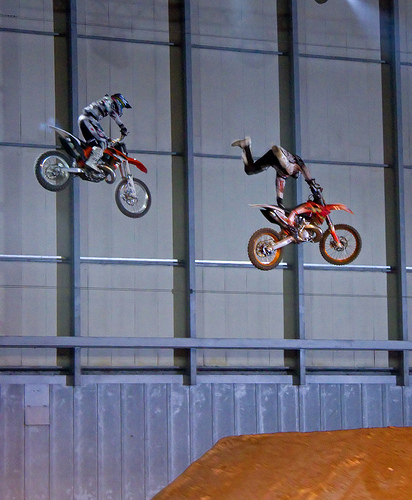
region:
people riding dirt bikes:
[18, 42, 409, 400]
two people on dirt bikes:
[24, 42, 402, 325]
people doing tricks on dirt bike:
[26, 40, 386, 301]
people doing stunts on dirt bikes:
[9, 42, 341, 281]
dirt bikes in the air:
[45, 43, 372, 265]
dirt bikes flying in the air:
[37, 33, 404, 327]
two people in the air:
[29, 24, 405, 327]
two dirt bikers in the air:
[30, 27, 411, 353]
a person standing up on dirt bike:
[12, 80, 238, 289]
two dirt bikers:
[30, 44, 380, 327]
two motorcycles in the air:
[23, 66, 377, 285]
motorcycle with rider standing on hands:
[232, 125, 371, 284]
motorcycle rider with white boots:
[31, 74, 157, 220]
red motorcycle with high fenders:
[244, 188, 364, 279]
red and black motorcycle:
[28, 83, 168, 227]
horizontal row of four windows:
[1, 264, 406, 375]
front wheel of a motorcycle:
[111, 173, 153, 217]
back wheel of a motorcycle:
[27, 144, 78, 194]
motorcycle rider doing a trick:
[224, 129, 369, 280]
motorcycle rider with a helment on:
[31, 82, 161, 220]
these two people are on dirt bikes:
[25, 79, 366, 280]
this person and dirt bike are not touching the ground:
[29, 77, 159, 229]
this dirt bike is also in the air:
[218, 117, 366, 294]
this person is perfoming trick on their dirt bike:
[233, 103, 315, 207]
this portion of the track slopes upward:
[193, 421, 403, 495]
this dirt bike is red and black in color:
[56, 129, 146, 180]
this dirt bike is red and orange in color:
[252, 195, 360, 245]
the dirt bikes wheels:
[241, 223, 374, 274]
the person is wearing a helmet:
[97, 86, 137, 116]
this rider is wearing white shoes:
[225, 129, 260, 157]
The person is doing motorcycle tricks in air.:
[226, 126, 364, 281]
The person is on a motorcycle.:
[35, 81, 164, 218]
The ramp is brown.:
[195, 403, 403, 492]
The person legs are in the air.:
[220, 114, 315, 192]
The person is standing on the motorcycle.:
[57, 90, 159, 223]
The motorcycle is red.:
[266, 187, 350, 224]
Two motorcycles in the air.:
[26, 87, 364, 320]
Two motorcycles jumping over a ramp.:
[42, 87, 388, 465]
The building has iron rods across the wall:
[15, 238, 226, 285]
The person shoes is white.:
[212, 127, 266, 155]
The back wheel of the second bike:
[26, 144, 74, 196]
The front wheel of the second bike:
[104, 175, 165, 223]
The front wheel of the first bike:
[314, 223, 368, 267]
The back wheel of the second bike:
[236, 222, 285, 272]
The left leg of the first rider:
[227, 131, 257, 176]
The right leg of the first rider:
[268, 144, 300, 183]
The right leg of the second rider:
[83, 139, 104, 175]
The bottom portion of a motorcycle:
[241, 226, 363, 270]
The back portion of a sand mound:
[148, 432, 231, 499]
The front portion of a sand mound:
[230, 416, 411, 498]